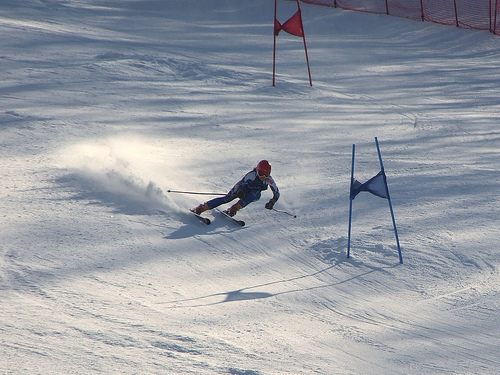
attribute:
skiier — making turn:
[162, 156, 299, 234]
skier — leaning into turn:
[227, 149, 286, 222]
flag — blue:
[344, 165, 401, 210]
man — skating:
[193, 159, 289, 221]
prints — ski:
[246, 264, 485, 344]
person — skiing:
[181, 157, 282, 222]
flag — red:
[275, 7, 322, 84]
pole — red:
[270, 0, 277, 86]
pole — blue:
[344, 142, 360, 264]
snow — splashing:
[73, 265, 142, 322]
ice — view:
[28, 232, 294, 372]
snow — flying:
[13, 7, 218, 373]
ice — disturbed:
[1, 0, 498, 372]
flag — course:
[345, 134, 405, 269]